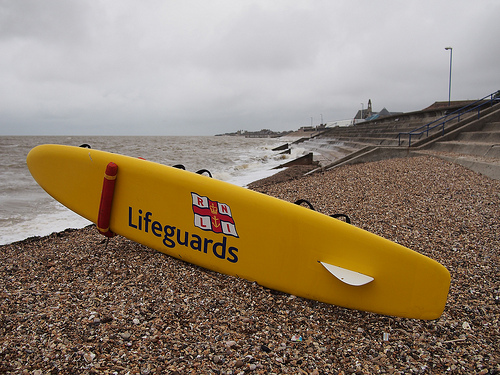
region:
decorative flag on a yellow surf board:
[178, 178, 260, 255]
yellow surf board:
[17, 126, 479, 357]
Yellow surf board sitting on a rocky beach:
[15, 124, 464, 348]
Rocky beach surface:
[14, 204, 184, 374]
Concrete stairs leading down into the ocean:
[279, 101, 459, 228]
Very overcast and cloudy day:
[66, 35, 423, 213]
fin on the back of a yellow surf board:
[261, 150, 452, 351]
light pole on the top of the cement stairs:
[428, 21, 489, 139]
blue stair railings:
[369, 73, 479, 186]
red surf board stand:
[41, 82, 202, 296]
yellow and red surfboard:
[40, 150, 420, 320]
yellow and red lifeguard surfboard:
[44, 154, 398, 322]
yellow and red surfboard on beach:
[51, 149, 422, 320]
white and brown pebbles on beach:
[20, 258, 199, 348]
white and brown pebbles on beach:
[185, 297, 297, 345]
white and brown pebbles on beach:
[352, 167, 454, 224]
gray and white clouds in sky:
[17, 18, 319, 111]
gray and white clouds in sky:
[311, 5, 418, 86]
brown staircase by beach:
[312, 121, 434, 141]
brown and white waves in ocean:
[137, 137, 231, 160]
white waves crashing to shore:
[213, 142, 273, 178]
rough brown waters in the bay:
[88, 121, 193, 146]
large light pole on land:
[435, 32, 462, 97]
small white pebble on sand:
[130, 315, 140, 332]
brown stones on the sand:
[354, 160, 450, 221]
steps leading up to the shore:
[282, 117, 371, 169]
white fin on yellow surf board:
[292, 248, 427, 304]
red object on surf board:
[95, 146, 128, 245]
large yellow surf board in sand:
[33, 132, 455, 339]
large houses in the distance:
[336, 85, 391, 130]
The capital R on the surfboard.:
[193, 194, 208, 210]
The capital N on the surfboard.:
[217, 199, 233, 214]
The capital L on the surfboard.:
[193, 215, 211, 231]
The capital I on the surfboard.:
[222, 218, 236, 234]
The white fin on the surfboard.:
[313, 260, 384, 294]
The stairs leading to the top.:
[306, 100, 498, 206]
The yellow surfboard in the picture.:
[27, 137, 462, 327]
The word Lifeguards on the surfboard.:
[120, 200, 238, 267]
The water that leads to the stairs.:
[6, 131, 306, 211]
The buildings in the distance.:
[317, 90, 388, 125]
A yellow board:
[174, 103, 399, 284]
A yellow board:
[253, 146, 387, 363]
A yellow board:
[153, 114, 323, 366]